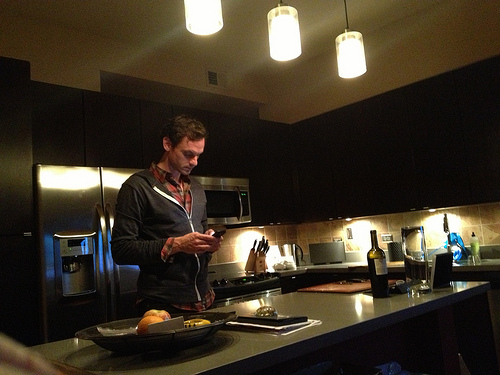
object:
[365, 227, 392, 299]
bottle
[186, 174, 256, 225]
microwave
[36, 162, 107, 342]
refrigerator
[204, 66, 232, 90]
vent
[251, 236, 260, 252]
knives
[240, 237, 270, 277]
wooden block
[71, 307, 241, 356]
bowl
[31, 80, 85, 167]
cabinet door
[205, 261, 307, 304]
stove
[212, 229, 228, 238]
cell phone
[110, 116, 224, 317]
man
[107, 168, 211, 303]
jacket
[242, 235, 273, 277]
knife holder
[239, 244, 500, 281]
countertop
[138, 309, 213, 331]
fruit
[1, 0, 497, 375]
kitchen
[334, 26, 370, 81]
light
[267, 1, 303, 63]
light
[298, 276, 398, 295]
cutting board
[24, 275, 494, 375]
countertop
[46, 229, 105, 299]
water and ice maker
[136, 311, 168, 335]
orange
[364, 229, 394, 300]
wine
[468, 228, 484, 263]
bottle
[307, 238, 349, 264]
toaster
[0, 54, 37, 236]
cabinet door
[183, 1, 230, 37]
lights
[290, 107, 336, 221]
cabinet door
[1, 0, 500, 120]
ceiling